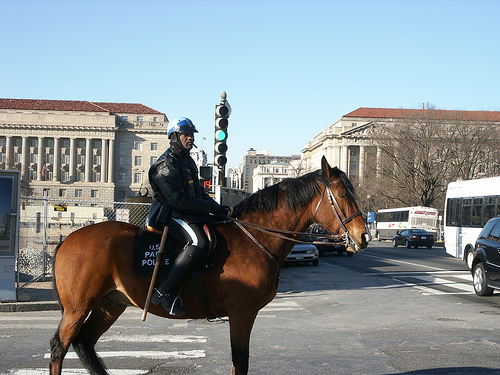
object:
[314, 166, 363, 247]
bridle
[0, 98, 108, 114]
roof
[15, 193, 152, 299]
fence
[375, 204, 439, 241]
bus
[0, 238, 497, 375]
street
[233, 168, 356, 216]
mane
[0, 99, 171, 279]
building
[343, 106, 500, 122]
roof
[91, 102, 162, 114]
roof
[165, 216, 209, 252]
pants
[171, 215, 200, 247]
stripe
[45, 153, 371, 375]
horse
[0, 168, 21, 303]
box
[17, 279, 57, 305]
sidewalk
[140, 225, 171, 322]
baton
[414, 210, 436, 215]
stripe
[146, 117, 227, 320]
officer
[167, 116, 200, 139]
helmet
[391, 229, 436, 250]
car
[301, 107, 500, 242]
building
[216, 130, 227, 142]
light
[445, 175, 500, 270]
bus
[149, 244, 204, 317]
boots